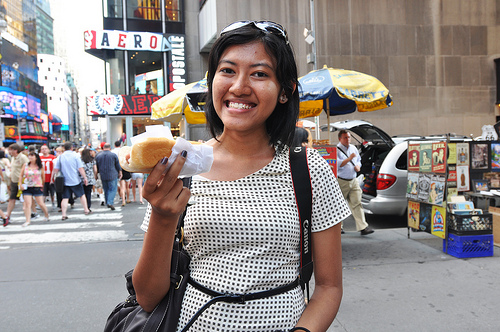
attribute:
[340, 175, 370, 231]
pants — tan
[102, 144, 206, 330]
purse — black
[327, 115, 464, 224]
car — silver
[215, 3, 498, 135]
wall — side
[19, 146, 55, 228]
woman — white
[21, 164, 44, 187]
sleeveless top — pink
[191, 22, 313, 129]
head — woman's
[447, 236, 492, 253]
carton — blue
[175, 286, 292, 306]
belt — womans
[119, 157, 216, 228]
hand — woman's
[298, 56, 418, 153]
umbrella — blue, yellow